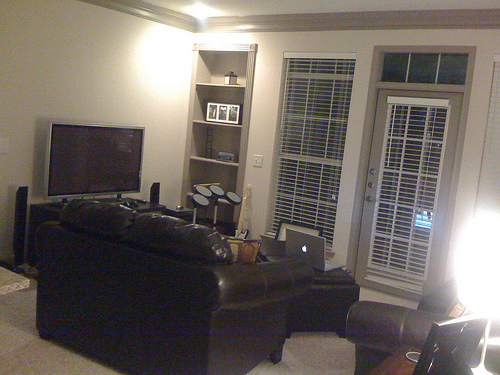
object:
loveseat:
[33, 198, 312, 375]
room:
[227, 125, 500, 374]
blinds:
[267, 52, 355, 255]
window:
[380, 47, 409, 82]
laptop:
[283, 227, 346, 271]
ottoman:
[257, 241, 361, 338]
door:
[344, 43, 477, 301]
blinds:
[368, 95, 451, 294]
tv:
[47, 122, 148, 196]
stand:
[29, 196, 166, 261]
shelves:
[180, 43, 259, 233]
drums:
[189, 183, 242, 229]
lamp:
[453, 207, 500, 374]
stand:
[363, 344, 421, 374]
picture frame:
[410, 314, 487, 373]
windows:
[380, 52, 470, 85]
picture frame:
[204, 102, 242, 126]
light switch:
[251, 153, 264, 168]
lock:
[367, 166, 377, 174]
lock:
[366, 179, 376, 191]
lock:
[364, 194, 374, 204]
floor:
[0, 276, 420, 375]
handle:
[365, 195, 375, 205]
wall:
[0, 0, 193, 211]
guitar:
[235, 184, 251, 240]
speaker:
[11, 184, 29, 268]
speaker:
[150, 181, 162, 206]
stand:
[186, 205, 224, 230]